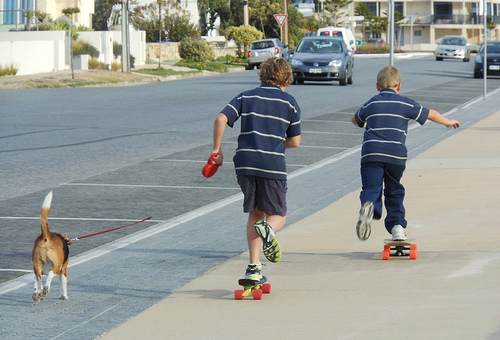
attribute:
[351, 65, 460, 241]
boy — skateboarding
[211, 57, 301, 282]
boy — skateboarding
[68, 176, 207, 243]
leash — red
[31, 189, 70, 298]
dog — running, brown, medium-sized, black, tan, white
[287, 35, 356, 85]
car — gray, driving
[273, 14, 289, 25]
sign — traingular, white, red, yield sign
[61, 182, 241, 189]
line — white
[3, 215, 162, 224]
line — white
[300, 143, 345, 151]
line — white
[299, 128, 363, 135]
line — white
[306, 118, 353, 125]
line — white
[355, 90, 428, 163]
shirt — striped, blue, navy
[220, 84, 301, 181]
shirt — striped, blue, navy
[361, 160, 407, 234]
pants — blue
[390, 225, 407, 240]
shoe — white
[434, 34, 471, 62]
car — silver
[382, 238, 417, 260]
skateboard — wooden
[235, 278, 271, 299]
skateboard — black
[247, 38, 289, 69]
car — parked, silver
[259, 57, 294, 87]
hair — brown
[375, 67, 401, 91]
hair — brown, blonde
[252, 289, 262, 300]
wheel — red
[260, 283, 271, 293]
wheel — red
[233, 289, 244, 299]
wheel — red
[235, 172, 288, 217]
shorts — blue